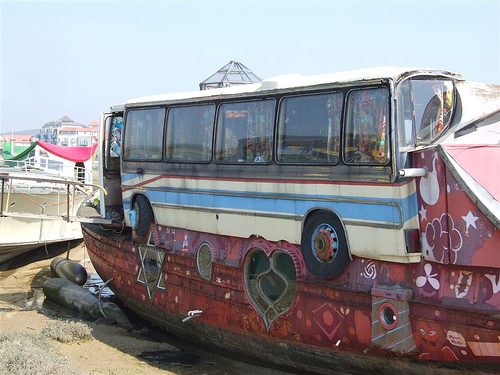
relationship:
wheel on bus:
[300, 209, 348, 277] [98, 67, 464, 275]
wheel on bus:
[131, 195, 150, 235] [98, 67, 464, 275]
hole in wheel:
[328, 229, 333, 234] [300, 209, 348, 277]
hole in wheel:
[333, 237, 338, 244] [300, 209, 348, 277]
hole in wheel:
[322, 225, 327, 232] [300, 209, 348, 277]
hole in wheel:
[333, 248, 338, 253] [300, 209, 348, 277]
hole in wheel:
[328, 255, 333, 263] [300, 209, 348, 277]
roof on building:
[37, 140, 98, 164] [6, 140, 98, 191]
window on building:
[48, 159, 64, 172] [6, 140, 98, 191]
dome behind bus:
[199, 59, 262, 91] [98, 67, 464, 275]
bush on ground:
[0, 327, 63, 372] [1, 241, 307, 374]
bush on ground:
[43, 318, 94, 344] [1, 241, 307, 374]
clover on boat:
[414, 262, 440, 290] [80, 67, 498, 373]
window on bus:
[122, 106, 164, 165] [98, 67, 464, 275]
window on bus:
[164, 103, 214, 163] [98, 67, 464, 275]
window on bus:
[214, 98, 277, 163] [98, 67, 464, 275]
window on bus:
[276, 94, 345, 164] [98, 67, 464, 275]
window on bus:
[343, 86, 394, 166] [98, 67, 464, 275]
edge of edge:
[377, 302, 399, 329] [376, 302, 400, 331]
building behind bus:
[6, 140, 98, 191] [98, 67, 464, 275]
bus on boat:
[98, 67, 464, 275] [80, 67, 498, 373]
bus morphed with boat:
[98, 67, 464, 275] [80, 67, 498, 373]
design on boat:
[310, 298, 343, 341] [80, 67, 498, 373]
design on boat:
[425, 213, 463, 263] [80, 67, 498, 373]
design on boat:
[361, 261, 377, 280] [80, 67, 498, 373]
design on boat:
[419, 150, 441, 205] [80, 67, 498, 373]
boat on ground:
[80, 67, 498, 373] [1, 241, 307, 374]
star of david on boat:
[134, 231, 167, 306] [80, 67, 498, 373]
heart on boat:
[241, 245, 300, 335] [80, 67, 498, 373]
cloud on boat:
[425, 213, 463, 263] [80, 67, 498, 373]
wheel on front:
[131, 195, 150, 235] [98, 97, 154, 235]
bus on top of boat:
[98, 67, 464, 275] [80, 67, 498, 373]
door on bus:
[101, 113, 126, 221] [98, 67, 464, 275]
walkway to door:
[2, 171, 116, 225] [101, 113, 126, 221]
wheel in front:
[131, 195, 150, 235] [98, 97, 154, 235]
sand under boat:
[2, 299, 301, 373] [80, 67, 498, 373]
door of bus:
[101, 113, 126, 221] [98, 67, 464, 275]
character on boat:
[415, 319, 461, 364] [80, 67, 498, 373]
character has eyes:
[415, 319, 461, 364] [418, 328, 435, 338]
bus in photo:
[98, 67, 464, 275] [5, 71, 497, 375]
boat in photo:
[80, 67, 498, 373] [20, 49, 89, 208]